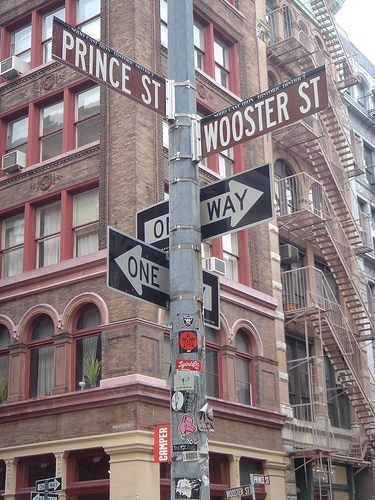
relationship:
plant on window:
[69, 354, 115, 406] [54, 292, 114, 392]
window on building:
[26, 313, 53, 400] [0, 0, 375, 499]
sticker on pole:
[181, 314, 194, 327] [134, 8, 227, 494]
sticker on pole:
[175, 328, 200, 355] [134, 8, 227, 494]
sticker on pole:
[171, 357, 204, 372] [134, 8, 227, 494]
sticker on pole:
[171, 368, 196, 393] [134, 8, 227, 494]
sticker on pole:
[168, 390, 184, 411] [134, 8, 227, 494]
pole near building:
[164, 0, 209, 499] [3, 0, 281, 500]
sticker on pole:
[178, 329, 197, 353] [164, 0, 209, 499]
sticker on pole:
[171, 390, 186, 412] [164, 0, 209, 499]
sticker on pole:
[177, 313, 197, 327] [164, 0, 209, 499]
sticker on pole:
[173, 444, 197, 450] [164, 0, 209, 499]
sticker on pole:
[174, 360, 200, 370] [164, 0, 209, 499]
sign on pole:
[132, 160, 275, 250] [132, 18, 248, 497]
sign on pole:
[103, 223, 222, 330] [132, 18, 248, 497]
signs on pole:
[44, 15, 349, 158] [161, 11, 212, 338]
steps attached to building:
[264, 1, 372, 467] [0, 0, 375, 499]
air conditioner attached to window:
[0, 55, 31, 81] [0, 10, 36, 82]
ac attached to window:
[1, 148, 26, 174] [0, 102, 32, 178]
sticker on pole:
[178, 329, 197, 352] [165, 0, 213, 499]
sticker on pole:
[173, 309, 202, 332] [165, 0, 213, 499]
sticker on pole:
[170, 368, 197, 392] [165, 0, 213, 499]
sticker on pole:
[174, 410, 201, 446] [165, 0, 213, 499]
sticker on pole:
[169, 473, 209, 499] [165, 0, 213, 499]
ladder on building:
[264, 0, 374, 462] [0, 0, 375, 499]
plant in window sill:
[69, 353, 117, 399] [72, 377, 99, 387]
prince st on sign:
[59, 31, 168, 113] [50, 14, 175, 117]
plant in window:
[81, 338, 114, 397] [66, 300, 111, 396]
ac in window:
[1, 148, 26, 174] [3, 112, 29, 169]